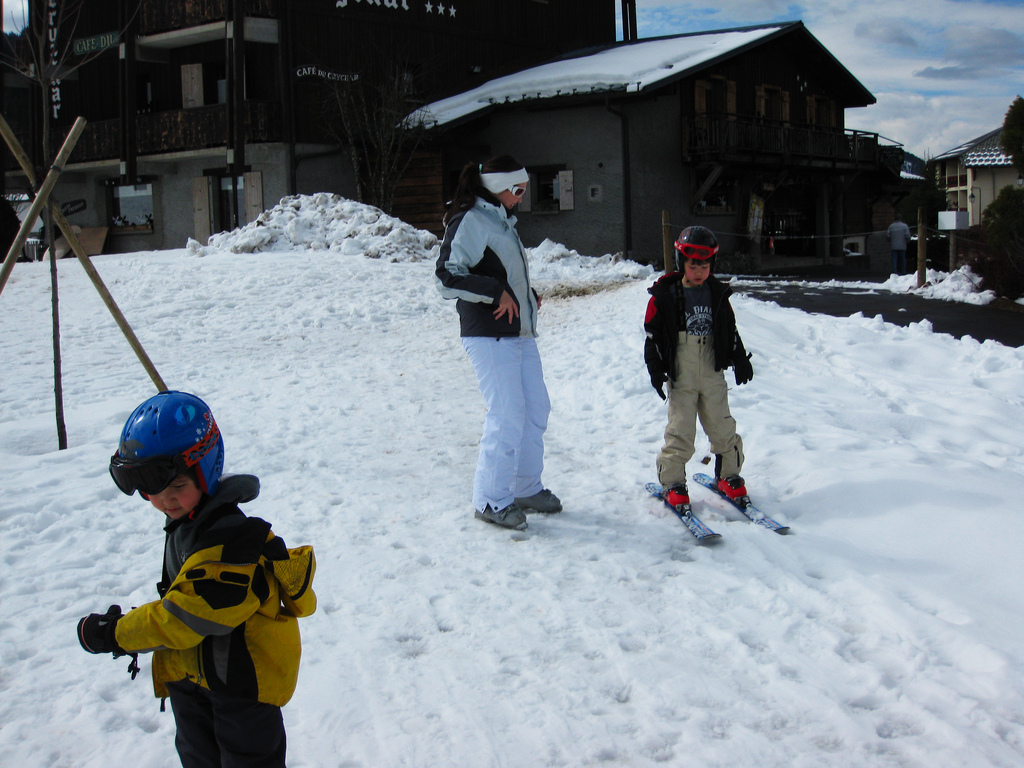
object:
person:
[644, 225, 753, 508]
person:
[71, 390, 317, 768]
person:
[431, 154, 562, 530]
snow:
[6, 149, 1022, 765]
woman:
[433, 157, 562, 531]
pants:
[460, 328, 551, 514]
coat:
[434, 189, 541, 338]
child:
[114, 475, 321, 706]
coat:
[113, 505, 321, 707]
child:
[77, 390, 316, 767]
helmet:
[108, 390, 226, 502]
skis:
[640, 468, 790, 548]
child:
[641, 226, 757, 510]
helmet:
[674, 226, 719, 273]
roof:
[391, 19, 877, 131]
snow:
[395, 22, 783, 133]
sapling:
[0, 0, 138, 456]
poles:
[2, 117, 179, 450]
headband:
[480, 168, 530, 194]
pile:
[186, 193, 441, 258]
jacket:
[115, 471, 320, 722]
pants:
[656, 331, 745, 492]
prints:
[0, 238, 1021, 764]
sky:
[2, 0, 1021, 163]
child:
[641, 224, 790, 545]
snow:
[269, 191, 342, 252]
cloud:
[610, 0, 1024, 159]